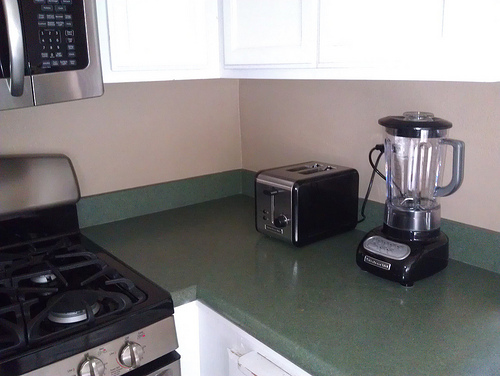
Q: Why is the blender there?
A: To blend food.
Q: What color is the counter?
A: Green.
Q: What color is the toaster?
A: Chrome and black.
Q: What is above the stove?
A: A microwave.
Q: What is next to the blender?
A: A toaster.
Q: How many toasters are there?
A: 1.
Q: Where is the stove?
A: On the left side of the photo.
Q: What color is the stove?
A: Black and chrome.